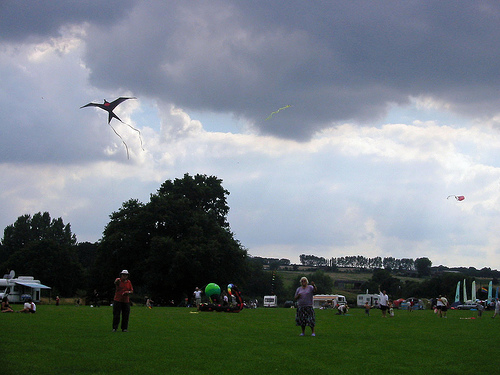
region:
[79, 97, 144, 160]
Large black kite with two ribbons coming off it.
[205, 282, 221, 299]
A green round ball.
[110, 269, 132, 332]
Person standing in a white cap and orange shirt.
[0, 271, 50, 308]
White camper with awning and satellite on top.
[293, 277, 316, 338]
Large person standing in black and white shorts pointing.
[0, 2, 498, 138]
Dark clouds in the top sky.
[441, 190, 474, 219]
Small barrel kite in the air the air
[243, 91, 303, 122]
Streamer kite is yellow in the sky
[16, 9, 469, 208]
Dark rain clouds are in the sky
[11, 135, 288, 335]
Tall trees in the back are near the campers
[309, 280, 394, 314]
Campers seen in the distance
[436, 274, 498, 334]
Large models in the park field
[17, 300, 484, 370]
Field has green grass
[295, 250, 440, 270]
Treeline is in the distance on the hillside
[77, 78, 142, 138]
kite in air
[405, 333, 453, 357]
short green and yellow grass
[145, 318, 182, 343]
short green and yellow grass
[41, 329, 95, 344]
short green and yellow grass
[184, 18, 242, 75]
white clouds in blue sky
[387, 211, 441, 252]
white clouds in blue sky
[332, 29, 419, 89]
white clouds in blue sky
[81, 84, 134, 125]
kite in sky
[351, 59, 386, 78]
white clouds in blue sky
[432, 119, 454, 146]
white clouds in blue sky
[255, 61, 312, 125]
white clouds in blue sky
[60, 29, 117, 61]
white clouds in blue sky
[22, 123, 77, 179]
white clouds in blue sky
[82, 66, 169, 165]
a kite in the sky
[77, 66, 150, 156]
a kite in the air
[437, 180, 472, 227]
a kite in the sky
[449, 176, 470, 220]
a kite in the air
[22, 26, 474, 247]
a sky with white clouds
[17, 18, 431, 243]
a blue sky with white clouds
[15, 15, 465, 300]
a blue sky with clouds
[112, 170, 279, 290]
leaves on a tree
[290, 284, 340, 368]
person standing in a field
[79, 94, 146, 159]
A kite flying in the sky.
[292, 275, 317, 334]
A person looking in the direction of the camera.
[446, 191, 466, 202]
A kite flying in the background.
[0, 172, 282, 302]
A group of trees.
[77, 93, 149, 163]
bird kite in the sky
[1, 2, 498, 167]
sky with dark storm clouds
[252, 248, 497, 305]
a hill of trees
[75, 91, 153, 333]
person flying a kite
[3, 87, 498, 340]
people flying kites during the day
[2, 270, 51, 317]
white camper with a large awning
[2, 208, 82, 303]
white camper in front of a group of trees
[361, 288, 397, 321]
mother walking two children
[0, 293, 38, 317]
group of people sitting on the grass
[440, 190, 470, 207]
a red kite in the sky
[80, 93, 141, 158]
Kite that resembles a bird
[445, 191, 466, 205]
Kite flying in th distance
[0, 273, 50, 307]
Mobile cmper in front of the tree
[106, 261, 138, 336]
Man with a red shirt flying a kite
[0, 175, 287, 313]
Trees at the edge of the field.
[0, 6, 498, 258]
Clouds in the sky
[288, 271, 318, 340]
Person standing in the grass.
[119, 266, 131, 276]
White hat on man's head